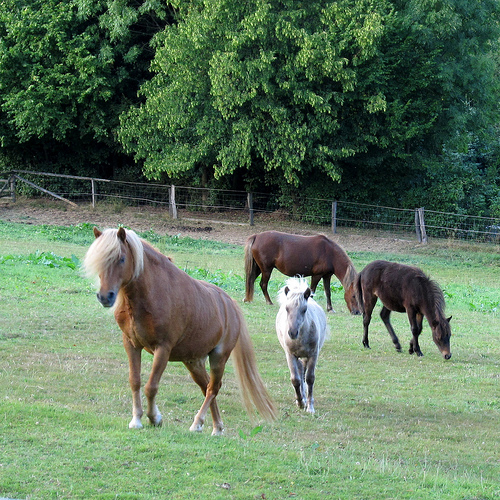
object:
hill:
[0, 196, 499, 499]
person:
[193, 123, 396, 185]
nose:
[95, 291, 114, 303]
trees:
[0, 0, 152, 157]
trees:
[114, 0, 249, 214]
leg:
[142, 341, 170, 430]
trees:
[205, 0, 319, 197]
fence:
[0, 169, 498, 245]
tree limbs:
[0, 4, 46, 45]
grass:
[0, 203, 498, 499]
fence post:
[331, 197, 336, 238]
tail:
[230, 299, 279, 431]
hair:
[78, 224, 145, 284]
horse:
[273, 273, 330, 418]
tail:
[243, 233, 258, 302]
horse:
[352, 259, 450, 361]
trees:
[281, 0, 397, 201]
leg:
[120, 330, 144, 431]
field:
[0, 202, 499, 497]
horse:
[241, 229, 364, 316]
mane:
[409, 266, 453, 332]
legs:
[378, 306, 401, 354]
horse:
[77, 225, 278, 438]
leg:
[361, 296, 376, 350]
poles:
[417, 208, 427, 242]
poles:
[245, 192, 253, 227]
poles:
[166, 183, 178, 221]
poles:
[88, 177, 96, 210]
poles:
[8, 172, 16, 207]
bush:
[399, 158, 498, 241]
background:
[0, 0, 499, 499]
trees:
[436, 43, 498, 184]